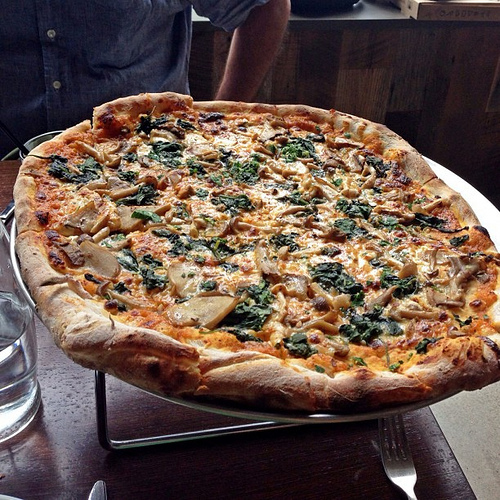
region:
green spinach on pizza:
[248, 285, 268, 307]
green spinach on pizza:
[293, 343, 308, 355]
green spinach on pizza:
[327, 270, 359, 292]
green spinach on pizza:
[356, 324, 376, 342]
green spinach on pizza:
[147, 275, 164, 287]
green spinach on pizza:
[137, 191, 147, 198]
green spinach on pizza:
[219, 198, 242, 208]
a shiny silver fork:
[359, 403, 445, 498]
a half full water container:
[0, 212, 67, 470]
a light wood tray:
[385, 0, 496, 29]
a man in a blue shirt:
[13, 0, 338, 160]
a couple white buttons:
[41, 20, 68, 96]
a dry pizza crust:
[70, 316, 360, 434]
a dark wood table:
[9, 145, 488, 495]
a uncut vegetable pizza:
[7, 102, 476, 429]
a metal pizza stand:
[79, 368, 481, 459]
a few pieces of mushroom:
[61, 199, 140, 291]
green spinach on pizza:
[313, 263, 356, 298]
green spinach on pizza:
[283, 333, 308, 355]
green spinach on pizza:
[147, 270, 168, 291]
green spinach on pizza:
[141, 207, 161, 220]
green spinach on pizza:
[238, 164, 255, 184]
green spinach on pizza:
[342, 203, 367, 216]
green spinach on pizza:
[53, 166, 73, 180]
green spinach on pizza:
[131, 195, 151, 203]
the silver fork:
[379, 420, 416, 498]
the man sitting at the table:
[2, 2, 285, 104]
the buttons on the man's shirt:
[35, 27, 63, 89]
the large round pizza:
[20, 96, 499, 408]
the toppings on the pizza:
[92, 145, 399, 325]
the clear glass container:
[1, 222, 38, 447]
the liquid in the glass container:
[1, 290, 40, 436]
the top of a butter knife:
[87, 480, 107, 499]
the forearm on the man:
[219, 0, 289, 100]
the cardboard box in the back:
[397, 1, 498, 23]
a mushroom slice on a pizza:
[156, 286, 240, 332]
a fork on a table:
[375, 412, 425, 499]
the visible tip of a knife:
[80, 474, 109, 497]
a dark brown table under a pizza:
[0, 157, 483, 496]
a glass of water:
[0, 230, 55, 450]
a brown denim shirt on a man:
[2, 0, 307, 159]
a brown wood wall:
[272, 33, 498, 170]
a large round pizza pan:
[10, 98, 496, 421]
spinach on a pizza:
[300, 257, 378, 309]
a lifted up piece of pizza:
[92, 87, 202, 200]